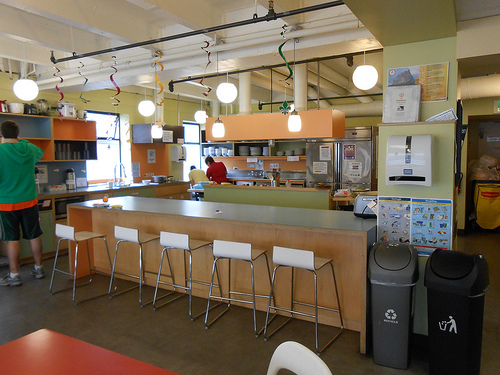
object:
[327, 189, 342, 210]
stand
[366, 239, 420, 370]
bin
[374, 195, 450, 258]
chart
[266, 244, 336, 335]
chair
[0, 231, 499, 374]
floor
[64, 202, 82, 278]
edge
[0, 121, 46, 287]
man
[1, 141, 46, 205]
jacket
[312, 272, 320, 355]
metal legs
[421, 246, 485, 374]
garbage cans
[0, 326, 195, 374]
table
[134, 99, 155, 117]
lights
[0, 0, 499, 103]
ceiling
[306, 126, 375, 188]
refrigerator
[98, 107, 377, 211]
kitchen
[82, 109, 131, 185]
window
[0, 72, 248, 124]
wall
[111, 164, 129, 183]
faucet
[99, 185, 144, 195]
sink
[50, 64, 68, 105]
ribbons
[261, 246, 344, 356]
chairs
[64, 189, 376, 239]
counter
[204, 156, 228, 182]
woman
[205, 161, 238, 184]
red shirt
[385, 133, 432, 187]
towel holder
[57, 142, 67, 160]
bottles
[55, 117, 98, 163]
shelf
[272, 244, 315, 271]
low backs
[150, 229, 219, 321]
chair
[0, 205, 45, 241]
shorts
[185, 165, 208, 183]
person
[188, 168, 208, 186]
yellow shirt